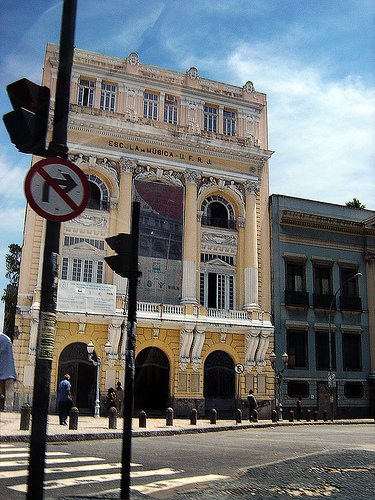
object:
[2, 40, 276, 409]
building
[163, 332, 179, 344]
brick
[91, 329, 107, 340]
brick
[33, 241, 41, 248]
brick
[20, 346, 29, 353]
brick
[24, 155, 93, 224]
sign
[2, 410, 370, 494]
street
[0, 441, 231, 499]
lines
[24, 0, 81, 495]
pole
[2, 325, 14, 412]
person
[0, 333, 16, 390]
left shoulder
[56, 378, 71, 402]
shirt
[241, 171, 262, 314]
columns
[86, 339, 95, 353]
street light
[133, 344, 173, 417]
doorway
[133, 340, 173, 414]
arch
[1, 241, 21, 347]
tree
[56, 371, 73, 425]
man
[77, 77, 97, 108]
window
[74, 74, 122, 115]
row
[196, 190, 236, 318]
window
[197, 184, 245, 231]
arch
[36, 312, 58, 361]
sign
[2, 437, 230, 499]
crosswalk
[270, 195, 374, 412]
building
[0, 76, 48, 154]
traffic lights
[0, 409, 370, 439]
sidewalk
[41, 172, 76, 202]
arrow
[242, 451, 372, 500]
holes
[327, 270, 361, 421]
poles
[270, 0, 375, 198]
sky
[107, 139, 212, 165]
name